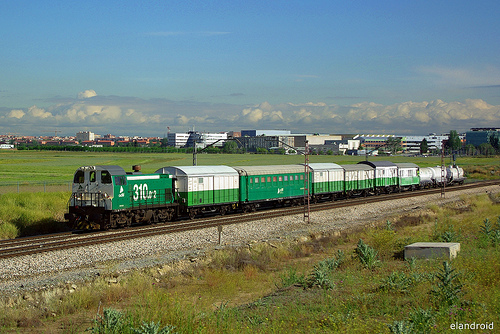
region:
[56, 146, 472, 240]
train on the tracks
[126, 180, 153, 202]
large white numbers on the side of the train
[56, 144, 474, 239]
green and white train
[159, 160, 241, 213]
green and white train car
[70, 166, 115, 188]
windows on the front of the train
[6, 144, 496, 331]
green grass on the ground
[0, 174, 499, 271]
gravel along the train tracks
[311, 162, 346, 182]
white paint on the top of the train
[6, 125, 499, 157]
buildings in the distance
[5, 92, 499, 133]
thick clouds in the sky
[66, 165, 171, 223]
front of the train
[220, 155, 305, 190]
car of the train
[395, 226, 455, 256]
stone in the grass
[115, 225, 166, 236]
train tracks on ground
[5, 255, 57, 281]
rocks near the tracks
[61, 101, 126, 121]
clouds in the sky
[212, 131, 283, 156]
buildings in the distance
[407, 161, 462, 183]
back of the train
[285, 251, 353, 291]
plants in the field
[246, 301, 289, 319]
grass in the field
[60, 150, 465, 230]
train going down the tracks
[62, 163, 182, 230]
train engine pulling cars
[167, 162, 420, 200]
several green and white box cars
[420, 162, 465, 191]
two silver tanker cars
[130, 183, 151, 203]
310 on the side of the engine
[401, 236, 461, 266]
concrete platform near the tracks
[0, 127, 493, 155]
lots of building in the distance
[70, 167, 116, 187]
front windows of the engine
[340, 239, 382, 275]
small bush near the tracks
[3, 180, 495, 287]
gravel along the tracks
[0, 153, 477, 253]
a train on a railroad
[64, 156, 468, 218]
train is color green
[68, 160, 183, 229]
front car is green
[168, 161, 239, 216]
car of train is green and white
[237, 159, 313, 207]
car of train is green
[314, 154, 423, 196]
cars of train are green and white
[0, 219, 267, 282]
gravel on side the railroad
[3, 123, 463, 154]
a city in front a railroad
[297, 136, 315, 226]
electrical poles on side the train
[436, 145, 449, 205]
electrical poles on side the train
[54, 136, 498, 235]
this is a freight train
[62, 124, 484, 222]
the train is green and white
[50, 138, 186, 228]
the engine is green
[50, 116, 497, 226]
the train is hauling white and green cars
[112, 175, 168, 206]
the numbers are white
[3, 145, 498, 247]
there is gravel on the side of the train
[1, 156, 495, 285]
the gravel is white and grey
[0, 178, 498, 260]
these are train tracks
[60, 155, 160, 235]
the front of the train is white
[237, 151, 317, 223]
this car is green and has various color windows